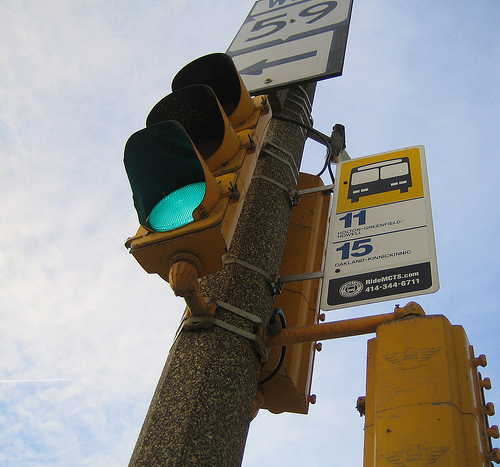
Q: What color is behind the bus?
A: Yellow.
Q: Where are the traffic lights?
A: On pole.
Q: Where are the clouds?
A: In the sky.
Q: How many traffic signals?
A: Three.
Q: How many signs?
A: Two.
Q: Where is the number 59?
A: Above the traffic signal.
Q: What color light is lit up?
A: Green.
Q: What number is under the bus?
A: 11.